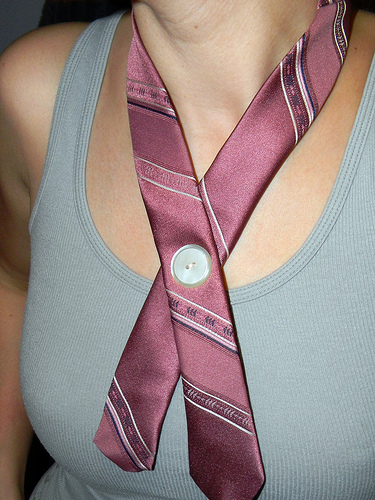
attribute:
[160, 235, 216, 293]
button — translucent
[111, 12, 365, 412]
tie — pink, silk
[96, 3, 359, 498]
tie — pink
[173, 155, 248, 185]
tie — purple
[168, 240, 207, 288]
white button — large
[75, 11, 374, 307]
collar — stitched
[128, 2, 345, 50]
neck — white, thin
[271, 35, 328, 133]
stripes — white, blue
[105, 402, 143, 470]
blue stripe — thin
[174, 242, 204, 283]
button — round, white, plastic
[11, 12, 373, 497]
shirt — green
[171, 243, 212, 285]
button — round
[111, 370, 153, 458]
stripe — white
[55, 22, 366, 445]
top — tank top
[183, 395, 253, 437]
stripe — thin, white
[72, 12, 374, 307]
stitching — gray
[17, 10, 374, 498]
tank top — gray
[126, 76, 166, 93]
stripe — white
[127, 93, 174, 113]
stripe — white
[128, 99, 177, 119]
stripe — blue